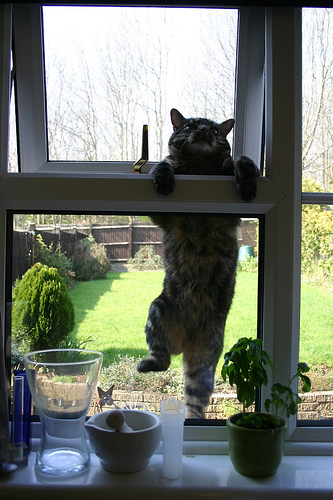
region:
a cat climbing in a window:
[136, 108, 259, 419]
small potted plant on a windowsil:
[220, 336, 311, 477]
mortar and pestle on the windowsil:
[83, 409, 161, 472]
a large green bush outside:
[11, 261, 74, 350]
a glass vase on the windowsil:
[22, 347, 102, 477]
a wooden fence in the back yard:
[13, 221, 257, 287]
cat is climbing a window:
[135, 106, 260, 419]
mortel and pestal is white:
[83, 408, 162, 473]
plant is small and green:
[222, 337, 312, 428]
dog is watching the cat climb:
[97, 384, 122, 412]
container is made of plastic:
[159, 398, 185, 480]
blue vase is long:
[12, 366, 33, 465]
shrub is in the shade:
[71, 233, 110, 282]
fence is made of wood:
[13, 223, 256, 281]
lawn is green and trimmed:
[59, 268, 331, 368]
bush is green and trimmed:
[13, 263, 74, 349]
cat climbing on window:
[142, 103, 229, 373]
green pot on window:
[234, 409, 290, 483]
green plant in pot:
[240, 341, 313, 434]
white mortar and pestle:
[40, 386, 155, 482]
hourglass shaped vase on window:
[35, 354, 100, 497]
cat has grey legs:
[142, 361, 227, 445]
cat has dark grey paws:
[131, 141, 274, 214]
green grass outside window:
[87, 290, 127, 345]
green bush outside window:
[7, 284, 101, 391]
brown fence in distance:
[103, 229, 150, 266]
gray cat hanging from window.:
[136, 108, 261, 419]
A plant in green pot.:
[220, 336, 311, 477]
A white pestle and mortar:
[82, 408, 161, 474]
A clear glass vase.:
[21, 348, 103, 476]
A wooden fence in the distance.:
[13, 222, 165, 280]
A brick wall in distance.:
[9, 372, 331, 419]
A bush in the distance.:
[67, 232, 112, 280]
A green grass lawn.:
[12, 270, 331, 367]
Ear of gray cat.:
[169, 108, 186, 132]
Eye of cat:
[183, 123, 195, 129]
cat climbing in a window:
[136, 108, 259, 419]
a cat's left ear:
[219, 115, 237, 135]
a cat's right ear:
[165, 107, 183, 126]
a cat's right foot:
[137, 325, 171, 375]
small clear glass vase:
[21, 349, 102, 478]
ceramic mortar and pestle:
[86, 408, 163, 473]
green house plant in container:
[217, 334, 310, 479]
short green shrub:
[10, 265, 77, 361]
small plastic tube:
[158, 399, 186, 479]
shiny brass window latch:
[132, 126, 155, 174]